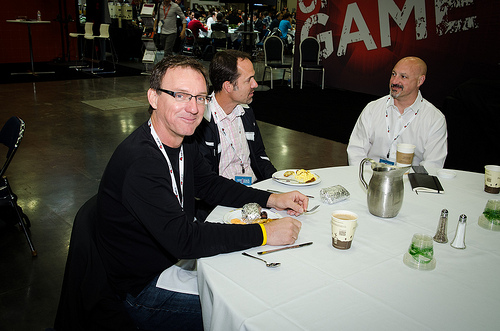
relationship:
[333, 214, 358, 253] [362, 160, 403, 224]
cup of coffee